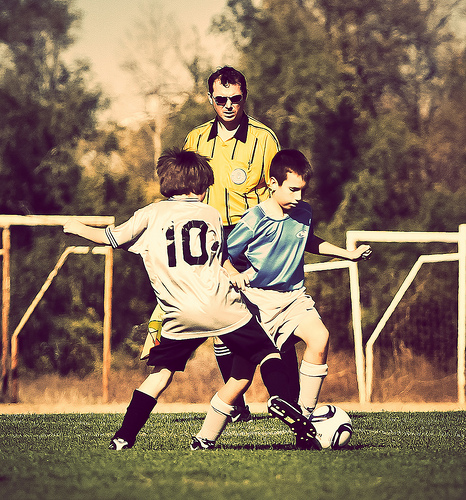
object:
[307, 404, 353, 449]
ball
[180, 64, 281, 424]
man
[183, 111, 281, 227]
shirt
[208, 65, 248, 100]
hair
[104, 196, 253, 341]
shirt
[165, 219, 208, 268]
number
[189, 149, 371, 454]
boy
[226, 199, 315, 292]
shirt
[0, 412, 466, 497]
grass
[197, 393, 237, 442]
socks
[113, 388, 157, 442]
socks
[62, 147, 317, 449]
kids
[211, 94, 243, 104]
sunglasses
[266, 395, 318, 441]
shoe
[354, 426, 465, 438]
line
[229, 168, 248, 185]
logo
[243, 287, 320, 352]
shorts